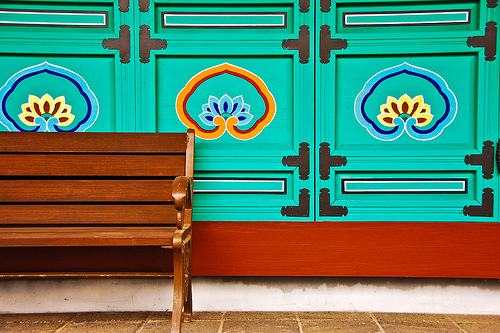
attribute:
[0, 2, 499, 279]
wall — green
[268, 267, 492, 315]
wall — white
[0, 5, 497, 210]
wall — decorative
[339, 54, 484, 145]
design — blue, yellow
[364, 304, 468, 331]
tile — brown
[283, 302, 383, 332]
tile — brown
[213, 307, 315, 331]
tile — brown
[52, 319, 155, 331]
tile — brown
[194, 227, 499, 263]
base — red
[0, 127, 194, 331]
bench — brown, wooden, dark brown, dark brown brown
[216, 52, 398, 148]
wall — light green, painted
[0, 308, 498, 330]
pavement — brick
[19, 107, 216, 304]
bench — brown, wooden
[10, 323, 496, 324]
grout — white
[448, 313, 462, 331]
grout — white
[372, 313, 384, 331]
grout — white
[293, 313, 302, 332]
grout — white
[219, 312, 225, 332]
grout — white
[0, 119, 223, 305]
bench — brown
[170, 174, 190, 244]
arm — decorative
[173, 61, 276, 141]
design — orange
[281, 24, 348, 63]
inlay — brown